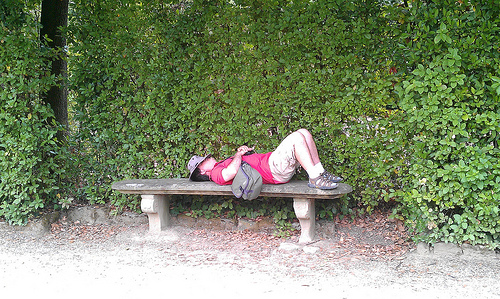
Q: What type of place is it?
A: It is a garden.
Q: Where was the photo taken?
A: It was taken at the garden.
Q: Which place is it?
A: It is a garden.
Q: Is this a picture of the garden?
A: Yes, it is showing the garden.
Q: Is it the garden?
A: Yes, it is the garden.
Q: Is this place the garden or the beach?
A: It is the garden.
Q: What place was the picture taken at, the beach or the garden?
A: It was taken at the garden.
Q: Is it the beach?
A: No, it is the garden.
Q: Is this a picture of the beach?
A: No, the picture is showing the garden.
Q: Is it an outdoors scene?
A: Yes, it is outdoors.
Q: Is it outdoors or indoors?
A: It is outdoors.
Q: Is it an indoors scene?
A: No, it is outdoors.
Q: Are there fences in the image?
A: No, there are no fences.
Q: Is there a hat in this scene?
A: Yes, there is a hat.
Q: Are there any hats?
A: Yes, there is a hat.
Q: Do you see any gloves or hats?
A: Yes, there is a hat.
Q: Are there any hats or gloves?
A: Yes, there is a hat.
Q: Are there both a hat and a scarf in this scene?
A: No, there is a hat but no scarves.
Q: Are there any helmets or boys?
A: No, there are no boys or helmets.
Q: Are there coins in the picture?
A: No, there are no coins.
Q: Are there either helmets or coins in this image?
A: No, there are no coins or helmets.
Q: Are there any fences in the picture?
A: No, there are no fences.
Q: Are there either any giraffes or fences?
A: No, there are no fences or giraffes.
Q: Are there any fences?
A: No, there are no fences.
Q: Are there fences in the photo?
A: No, there are no fences.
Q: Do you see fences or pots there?
A: No, there are no fences or pots.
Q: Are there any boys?
A: No, there are no boys.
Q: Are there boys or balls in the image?
A: No, there are no boys or balls.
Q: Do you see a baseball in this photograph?
A: No, there are no baseballs.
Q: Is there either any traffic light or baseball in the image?
A: No, there are no baseballs or traffic lights.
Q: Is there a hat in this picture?
A: Yes, there is a hat.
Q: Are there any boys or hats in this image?
A: Yes, there is a hat.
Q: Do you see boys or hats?
A: Yes, there is a hat.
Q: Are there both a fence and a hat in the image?
A: No, there is a hat but no fences.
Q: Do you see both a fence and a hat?
A: No, there is a hat but no fences.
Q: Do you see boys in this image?
A: No, there are no boys.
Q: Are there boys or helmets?
A: No, there are no boys or helmets.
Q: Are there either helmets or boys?
A: No, there are no boys or helmets.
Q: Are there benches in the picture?
A: Yes, there is a bench.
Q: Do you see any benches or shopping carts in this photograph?
A: Yes, there is a bench.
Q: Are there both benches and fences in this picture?
A: No, there is a bench but no fences.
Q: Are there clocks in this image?
A: No, there are no clocks.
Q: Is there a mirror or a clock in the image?
A: No, there are no clocks or mirrors.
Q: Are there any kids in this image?
A: No, there are no kids.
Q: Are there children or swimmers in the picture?
A: No, there are no children or swimmers.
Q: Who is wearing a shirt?
A: The man is wearing a shirt.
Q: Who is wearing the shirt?
A: The man is wearing a shirt.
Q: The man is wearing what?
A: The man is wearing a shirt.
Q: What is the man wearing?
A: The man is wearing a shirt.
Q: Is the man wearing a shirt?
A: Yes, the man is wearing a shirt.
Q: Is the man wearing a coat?
A: No, the man is wearing a shirt.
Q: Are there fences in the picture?
A: No, there are no fences.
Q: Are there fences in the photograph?
A: No, there are no fences.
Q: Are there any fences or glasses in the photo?
A: No, there are no fences or glasses.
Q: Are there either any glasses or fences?
A: No, there are no fences or glasses.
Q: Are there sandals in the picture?
A: Yes, there are sandals.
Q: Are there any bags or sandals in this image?
A: Yes, there are sandals.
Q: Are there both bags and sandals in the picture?
A: Yes, there are both sandals and a bag.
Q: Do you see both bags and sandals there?
A: Yes, there are both sandals and a bag.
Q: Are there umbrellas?
A: No, there are no umbrellas.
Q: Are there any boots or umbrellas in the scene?
A: No, there are no umbrellas or boots.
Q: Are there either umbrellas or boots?
A: No, there are no umbrellas or boots.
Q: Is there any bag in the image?
A: Yes, there is a bag.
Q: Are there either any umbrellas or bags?
A: Yes, there is a bag.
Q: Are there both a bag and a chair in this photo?
A: No, there is a bag but no chairs.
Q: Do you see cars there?
A: No, there are no cars.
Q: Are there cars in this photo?
A: No, there are no cars.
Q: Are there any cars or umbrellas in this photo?
A: No, there are no cars or umbrellas.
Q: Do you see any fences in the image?
A: No, there are no fences.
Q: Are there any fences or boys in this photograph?
A: No, there are no fences or boys.